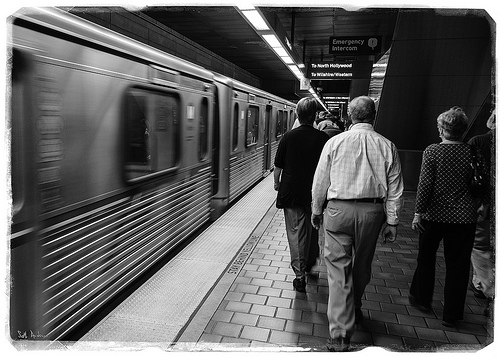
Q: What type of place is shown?
A: It is a station.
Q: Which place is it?
A: It is a station.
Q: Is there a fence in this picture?
A: No, there are no fences.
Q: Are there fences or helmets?
A: No, there are no fences or helmets.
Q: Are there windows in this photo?
A: Yes, there is a window.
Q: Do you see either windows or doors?
A: Yes, there is a window.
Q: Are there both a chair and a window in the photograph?
A: No, there is a window but no chairs.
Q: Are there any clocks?
A: No, there are no clocks.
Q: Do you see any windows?
A: Yes, there is a window.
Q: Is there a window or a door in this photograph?
A: Yes, there is a window.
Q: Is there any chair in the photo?
A: No, there are no chairs.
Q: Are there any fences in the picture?
A: No, there are no fences.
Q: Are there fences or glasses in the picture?
A: No, there are no fences or glasses.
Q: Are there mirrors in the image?
A: No, there are no mirrors.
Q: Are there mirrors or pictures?
A: No, there are no mirrors or pictures.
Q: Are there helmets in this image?
A: No, there are no helmets.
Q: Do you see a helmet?
A: No, there are no helmets.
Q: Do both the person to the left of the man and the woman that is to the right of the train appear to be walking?
A: Yes, both the person and the woman are walking.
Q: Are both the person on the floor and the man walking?
A: Yes, both the person and the man are walking.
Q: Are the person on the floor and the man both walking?
A: Yes, both the person and the man are walking.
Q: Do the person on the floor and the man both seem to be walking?
A: Yes, both the person and the man are walking.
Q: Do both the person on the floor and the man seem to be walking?
A: Yes, both the person and the man are walking.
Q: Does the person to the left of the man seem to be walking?
A: Yes, the person is walking.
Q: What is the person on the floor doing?
A: The person is walking.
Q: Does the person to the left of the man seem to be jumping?
A: No, the person is walking.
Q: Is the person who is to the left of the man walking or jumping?
A: The person is walking.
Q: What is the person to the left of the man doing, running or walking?
A: The person is walking.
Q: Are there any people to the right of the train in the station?
A: Yes, there is a person to the right of the train.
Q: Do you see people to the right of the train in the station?
A: Yes, there is a person to the right of the train.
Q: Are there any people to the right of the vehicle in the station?
A: Yes, there is a person to the right of the train.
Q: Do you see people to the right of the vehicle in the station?
A: Yes, there is a person to the right of the train.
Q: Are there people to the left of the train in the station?
A: No, the person is to the right of the train.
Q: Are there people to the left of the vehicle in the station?
A: No, the person is to the right of the train.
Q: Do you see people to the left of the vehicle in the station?
A: No, the person is to the right of the train.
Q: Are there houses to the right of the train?
A: No, there is a person to the right of the train.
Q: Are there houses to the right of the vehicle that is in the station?
A: No, there is a person to the right of the train.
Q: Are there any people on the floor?
A: Yes, there is a person on the floor.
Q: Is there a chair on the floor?
A: No, there is a person on the floor.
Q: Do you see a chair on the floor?
A: No, there is a person on the floor.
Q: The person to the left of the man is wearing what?
A: The person is wearing a shirt.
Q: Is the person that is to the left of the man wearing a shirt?
A: Yes, the person is wearing a shirt.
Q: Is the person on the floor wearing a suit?
A: No, the person is wearing a shirt.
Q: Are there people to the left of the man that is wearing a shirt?
A: Yes, there is a person to the left of the man.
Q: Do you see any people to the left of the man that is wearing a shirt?
A: Yes, there is a person to the left of the man.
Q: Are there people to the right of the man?
A: No, the person is to the left of the man.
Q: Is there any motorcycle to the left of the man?
A: No, there is a person to the left of the man.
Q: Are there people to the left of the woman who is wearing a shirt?
A: Yes, there is a person to the left of the woman.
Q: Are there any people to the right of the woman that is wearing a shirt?
A: No, the person is to the left of the woman.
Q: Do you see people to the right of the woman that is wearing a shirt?
A: No, the person is to the left of the woman.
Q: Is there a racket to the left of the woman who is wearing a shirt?
A: No, there is a person to the left of the woman.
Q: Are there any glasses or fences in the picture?
A: No, there are no fences or glasses.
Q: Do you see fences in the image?
A: No, there are no fences.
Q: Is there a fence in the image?
A: No, there are no fences.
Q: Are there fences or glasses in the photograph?
A: No, there are no fences or glasses.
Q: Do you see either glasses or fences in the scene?
A: No, there are no fences or glasses.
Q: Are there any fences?
A: No, there are no fences.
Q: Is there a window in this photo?
A: Yes, there is a window.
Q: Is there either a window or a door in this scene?
A: Yes, there is a window.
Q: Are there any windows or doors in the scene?
A: Yes, there is a window.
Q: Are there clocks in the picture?
A: No, there are no clocks.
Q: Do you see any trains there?
A: Yes, there is a train.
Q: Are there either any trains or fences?
A: Yes, there is a train.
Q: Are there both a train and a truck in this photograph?
A: No, there is a train but no trucks.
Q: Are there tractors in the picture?
A: No, there are no tractors.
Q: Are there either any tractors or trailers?
A: No, there are no tractors or trailers.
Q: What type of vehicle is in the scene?
A: The vehicle is a train.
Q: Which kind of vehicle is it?
A: The vehicle is a train.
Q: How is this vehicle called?
A: This is a train.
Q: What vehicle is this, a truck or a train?
A: This is a train.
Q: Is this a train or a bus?
A: This is a train.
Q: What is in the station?
A: The train is in the station.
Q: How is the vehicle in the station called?
A: The vehicle is a train.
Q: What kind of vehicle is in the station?
A: The vehicle is a train.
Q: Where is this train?
A: The train is in the station.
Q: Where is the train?
A: The train is in the station.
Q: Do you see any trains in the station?
A: Yes, there is a train in the station.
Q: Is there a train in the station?
A: Yes, there is a train in the station.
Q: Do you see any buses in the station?
A: No, there is a train in the station.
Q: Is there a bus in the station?
A: No, there is a train in the station.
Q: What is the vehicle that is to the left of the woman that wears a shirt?
A: The vehicle is a train.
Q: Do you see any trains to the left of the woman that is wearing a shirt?
A: Yes, there is a train to the left of the woman.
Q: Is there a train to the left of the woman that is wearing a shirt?
A: Yes, there is a train to the left of the woman.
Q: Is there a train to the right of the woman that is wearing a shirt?
A: No, the train is to the left of the woman.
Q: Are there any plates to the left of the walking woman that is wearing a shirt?
A: No, there is a train to the left of the woman.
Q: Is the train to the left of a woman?
A: Yes, the train is to the left of a woman.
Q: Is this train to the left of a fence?
A: No, the train is to the left of a woman.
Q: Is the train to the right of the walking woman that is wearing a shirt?
A: No, the train is to the left of the woman.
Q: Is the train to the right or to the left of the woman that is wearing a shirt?
A: The train is to the left of the woman.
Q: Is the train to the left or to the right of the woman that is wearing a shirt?
A: The train is to the left of the woman.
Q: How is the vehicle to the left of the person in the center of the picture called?
A: The vehicle is a train.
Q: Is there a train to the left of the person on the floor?
A: Yes, there is a train to the left of the person.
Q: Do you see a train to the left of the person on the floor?
A: Yes, there is a train to the left of the person.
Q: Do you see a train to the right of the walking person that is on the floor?
A: No, the train is to the left of the person.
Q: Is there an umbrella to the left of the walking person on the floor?
A: No, there is a train to the left of the person.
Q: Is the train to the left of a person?
A: Yes, the train is to the left of a person.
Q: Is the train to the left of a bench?
A: No, the train is to the left of a person.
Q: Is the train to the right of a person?
A: No, the train is to the left of a person.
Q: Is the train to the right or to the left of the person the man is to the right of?
A: The train is to the left of the person.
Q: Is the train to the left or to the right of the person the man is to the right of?
A: The train is to the left of the person.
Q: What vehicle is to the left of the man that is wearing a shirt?
A: The vehicle is a train.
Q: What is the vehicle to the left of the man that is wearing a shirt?
A: The vehicle is a train.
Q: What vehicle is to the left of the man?
A: The vehicle is a train.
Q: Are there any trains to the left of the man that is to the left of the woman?
A: Yes, there is a train to the left of the man.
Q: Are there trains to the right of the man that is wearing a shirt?
A: No, the train is to the left of the man.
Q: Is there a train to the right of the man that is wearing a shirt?
A: No, the train is to the left of the man.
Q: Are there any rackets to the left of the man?
A: No, there is a train to the left of the man.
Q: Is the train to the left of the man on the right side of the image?
A: Yes, the train is to the left of the man.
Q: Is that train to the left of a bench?
A: No, the train is to the left of the man.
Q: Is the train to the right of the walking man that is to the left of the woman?
A: No, the train is to the left of the man.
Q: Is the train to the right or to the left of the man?
A: The train is to the left of the man.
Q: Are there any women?
A: Yes, there is a woman.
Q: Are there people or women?
A: Yes, there is a woman.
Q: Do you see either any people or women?
A: Yes, there is a woman.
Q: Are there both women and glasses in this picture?
A: No, there is a woman but no glasses.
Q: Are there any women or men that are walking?
A: Yes, the woman is walking.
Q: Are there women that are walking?
A: Yes, there is a woman that is walking.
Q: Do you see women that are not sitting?
A: Yes, there is a woman that is walking .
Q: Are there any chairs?
A: No, there are no chairs.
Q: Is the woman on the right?
A: Yes, the woman is on the right of the image.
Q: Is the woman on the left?
A: No, the woman is on the right of the image.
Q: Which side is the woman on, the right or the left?
A: The woman is on the right of the image.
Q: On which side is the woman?
A: The woman is on the right of the image.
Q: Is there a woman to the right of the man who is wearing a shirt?
A: Yes, there is a woman to the right of the man.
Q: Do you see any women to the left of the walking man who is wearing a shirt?
A: No, the woman is to the right of the man.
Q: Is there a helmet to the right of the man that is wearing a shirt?
A: No, there is a woman to the right of the man.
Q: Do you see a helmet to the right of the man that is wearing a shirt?
A: No, there is a woman to the right of the man.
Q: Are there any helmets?
A: No, there are no helmets.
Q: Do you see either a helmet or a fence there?
A: No, there are no helmets or fences.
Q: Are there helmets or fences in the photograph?
A: No, there are no helmets or fences.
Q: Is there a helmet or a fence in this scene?
A: No, there are no helmets or fences.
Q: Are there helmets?
A: No, there are no helmets.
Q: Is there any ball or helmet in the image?
A: No, there are no helmets or balls.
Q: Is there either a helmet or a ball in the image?
A: No, there are no helmets or balls.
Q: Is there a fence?
A: No, there are no fences.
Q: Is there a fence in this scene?
A: No, there are no fences.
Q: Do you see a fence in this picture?
A: No, there are no fences.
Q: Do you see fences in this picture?
A: No, there are no fences.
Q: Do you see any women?
A: Yes, there is a woman.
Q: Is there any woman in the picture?
A: Yes, there is a woman.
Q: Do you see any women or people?
A: Yes, there is a woman.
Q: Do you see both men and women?
A: Yes, there are both a woman and a man.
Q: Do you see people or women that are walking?
A: Yes, the woman is walking.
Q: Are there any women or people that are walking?
A: Yes, the woman is walking.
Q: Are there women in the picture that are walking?
A: Yes, there is a woman that is walking.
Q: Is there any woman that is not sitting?
A: Yes, there is a woman that is walking.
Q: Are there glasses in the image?
A: No, there are no glasses.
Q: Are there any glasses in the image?
A: No, there are no glasses.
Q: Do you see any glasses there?
A: No, there are no glasses.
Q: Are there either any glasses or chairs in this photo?
A: No, there are no glasses or chairs.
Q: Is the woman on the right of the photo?
A: Yes, the woman is on the right of the image.